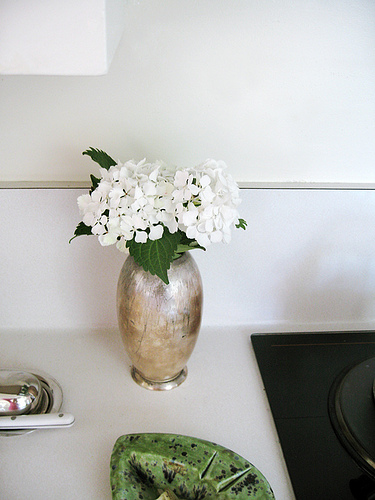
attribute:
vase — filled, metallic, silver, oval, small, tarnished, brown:
[116, 252, 204, 387]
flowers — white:
[76, 160, 239, 255]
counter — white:
[3, 328, 375, 498]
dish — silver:
[1, 370, 74, 433]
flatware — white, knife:
[3, 414, 79, 428]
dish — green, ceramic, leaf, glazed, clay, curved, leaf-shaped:
[109, 432, 269, 495]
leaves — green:
[81, 143, 115, 191]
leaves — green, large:
[127, 228, 200, 279]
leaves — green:
[72, 222, 102, 243]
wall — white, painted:
[7, 4, 372, 192]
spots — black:
[171, 442, 253, 493]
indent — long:
[199, 451, 218, 476]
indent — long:
[219, 463, 254, 490]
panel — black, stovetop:
[250, 324, 373, 495]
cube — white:
[4, 3, 129, 77]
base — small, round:
[128, 369, 193, 390]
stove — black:
[252, 330, 373, 496]